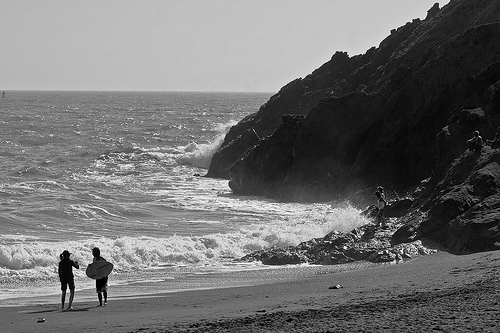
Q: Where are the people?
A: Beach.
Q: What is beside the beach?
A: Ocean.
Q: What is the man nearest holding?
A: A board.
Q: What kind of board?
A: A surfboard.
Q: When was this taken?
A: During the day.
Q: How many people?
A: Four.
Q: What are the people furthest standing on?
A: Rocks.